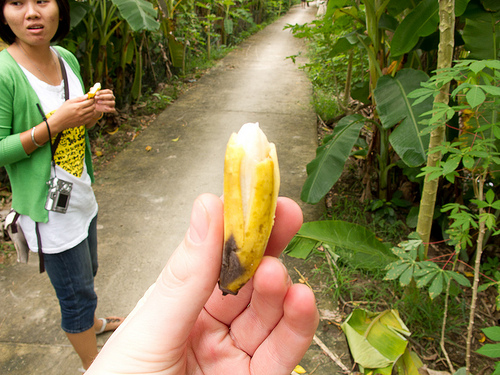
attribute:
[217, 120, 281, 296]
small banana — in the picture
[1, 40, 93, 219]
cardigan — green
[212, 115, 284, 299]
banana — tiny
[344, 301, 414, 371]
leaf — yellowed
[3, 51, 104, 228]
sweater — green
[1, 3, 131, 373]
woman — holding, capri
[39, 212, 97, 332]
jeans — blue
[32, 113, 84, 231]
digital — in the picture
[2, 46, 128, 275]
cardigan — green